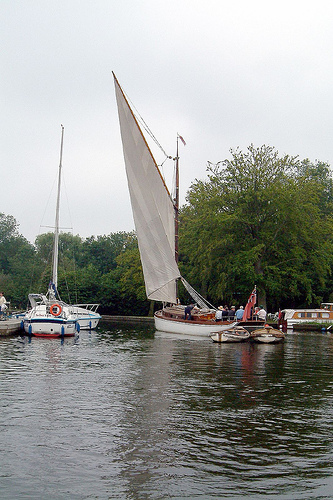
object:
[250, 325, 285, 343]
boat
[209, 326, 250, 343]
boat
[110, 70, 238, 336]
sailboat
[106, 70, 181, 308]
sail